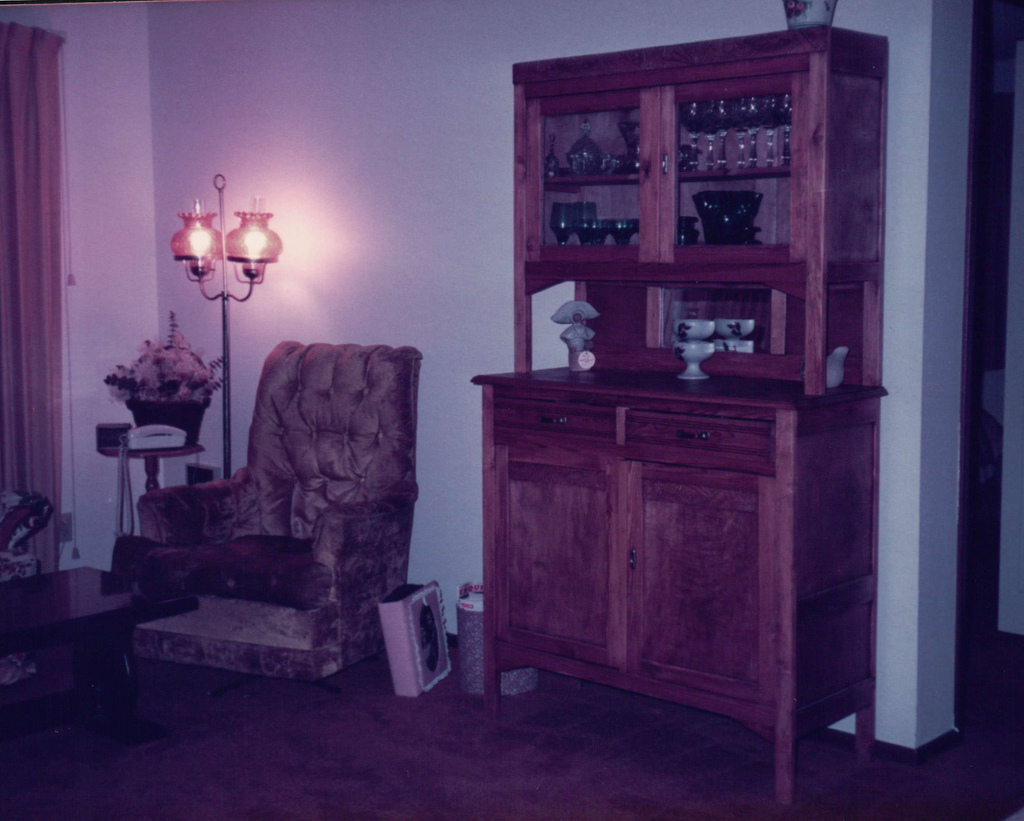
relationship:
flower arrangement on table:
[105, 325, 224, 447] [81, 405, 222, 555]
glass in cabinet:
[549, 191, 579, 246] [468, 12, 894, 812]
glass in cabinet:
[771, 105, 792, 166] [468, 12, 894, 812]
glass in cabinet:
[740, 98, 763, 169] [468, 12, 894, 812]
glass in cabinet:
[710, 96, 737, 174] [468, 12, 894, 812]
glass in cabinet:
[688, 98, 714, 178] [468, 12, 894, 812]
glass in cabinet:
[693, 96, 719, 183] [468, 12, 894, 812]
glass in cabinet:
[711, 93, 731, 173] [468, 12, 894, 812]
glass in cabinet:
[739, 98, 756, 171] [468, 12, 894, 812]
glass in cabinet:
[756, 93, 786, 173] [468, 12, 894, 812]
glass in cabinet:
[780, 86, 793, 175] [468, 12, 894, 812]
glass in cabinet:
[609, 210, 638, 248] [468, 12, 894, 812]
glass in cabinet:
[533, 192, 625, 249] [533, 104, 857, 377]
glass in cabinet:
[515, 176, 629, 268] [515, 176, 629, 268]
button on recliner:
[267, 360, 340, 412] [267, 360, 405, 649]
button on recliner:
[319, 368, 370, 413] [192, 368, 370, 644]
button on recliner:
[315, 374, 391, 429] [204, 374, 391, 627]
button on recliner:
[269, 417, 299, 450] [269, 417, 407, 689]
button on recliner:
[297, 404, 348, 443] [297, 404, 427, 658]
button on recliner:
[332, 394, 378, 461] [205, 394, 379, 658]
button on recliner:
[348, 403, 429, 470] [130, 403, 429, 619]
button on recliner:
[309, 447, 412, 517] [218, 333, 412, 517]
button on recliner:
[297, 444, 418, 496] [142, 328, 418, 496]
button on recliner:
[269, 466, 364, 531] [269, 333, 421, 531]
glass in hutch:
[515, 176, 668, 290] [515, 176, 668, 290]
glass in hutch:
[559, 207, 605, 249] [559, 207, 853, 517]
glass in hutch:
[546, 185, 686, 285] [546, 185, 686, 285]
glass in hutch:
[597, 197, 712, 280] [597, 197, 712, 280]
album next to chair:
[332, 567, 501, 688] [170, 369, 502, 687]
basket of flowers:
[103, 337, 271, 486] [103, 337, 271, 486]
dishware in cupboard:
[528, 159, 778, 420] [528, 159, 778, 420]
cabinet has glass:
[542, 192, 711, 310] [542, 192, 711, 310]